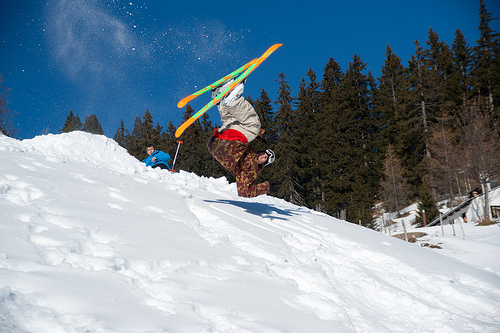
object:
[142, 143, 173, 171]
man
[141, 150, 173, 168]
jacket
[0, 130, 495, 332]
snow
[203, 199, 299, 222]
shadow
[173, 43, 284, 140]
skis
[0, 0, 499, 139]
sky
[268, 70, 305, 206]
evergreen tree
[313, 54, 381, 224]
trees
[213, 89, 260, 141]
pants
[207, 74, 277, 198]
man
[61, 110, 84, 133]
trees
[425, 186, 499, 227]
house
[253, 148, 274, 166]
head